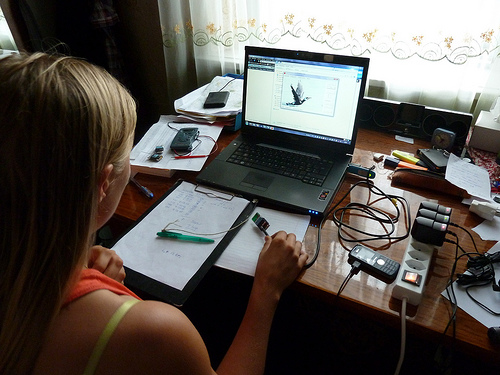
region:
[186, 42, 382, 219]
black laptop on desk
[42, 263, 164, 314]
girl has orange shirt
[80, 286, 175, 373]
girl has yellow bra strap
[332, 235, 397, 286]
cellphone charging on desk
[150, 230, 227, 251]
green ink pen on clip board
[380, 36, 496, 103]
curtain on the window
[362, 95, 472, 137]
docking station on desk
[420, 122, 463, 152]
small clock on desk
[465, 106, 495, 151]
box of tissues on desk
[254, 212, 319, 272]
girl is holding a cord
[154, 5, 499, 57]
floral white curtain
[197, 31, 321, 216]
laptop on the top of the table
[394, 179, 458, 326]
various charges on the electrical extension cord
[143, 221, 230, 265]
pen on the top of the clip board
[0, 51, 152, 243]
lady looking on the computer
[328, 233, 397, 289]
cellphone on the top of the table charging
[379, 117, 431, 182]
marker orange and yellow on the top of the table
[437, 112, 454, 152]
blue alarm clock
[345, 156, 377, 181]
USB plug on the computer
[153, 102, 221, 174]
recorder on the top of the paper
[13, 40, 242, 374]
young girl with green bra strap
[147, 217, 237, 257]
green ink pen on paper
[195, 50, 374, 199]
laptop with duck on the screen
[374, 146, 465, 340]
multiple outlet plug with 3 adapters in it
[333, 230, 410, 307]
cell phone charging on a desk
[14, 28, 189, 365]
young blonde girl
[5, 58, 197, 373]
blonde girl in orange top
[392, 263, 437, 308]
power light on electric outlet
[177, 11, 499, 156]
curtain with flowers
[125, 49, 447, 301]
multiple electronics on a desk together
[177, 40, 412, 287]
A laptop on the desk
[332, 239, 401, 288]
A cellphone on the desk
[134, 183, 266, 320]
A clipboard and pen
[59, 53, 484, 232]
Girl on the laptop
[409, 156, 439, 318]
A power strip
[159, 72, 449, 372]
Working on homework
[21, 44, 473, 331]
Studying for school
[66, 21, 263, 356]
Girl on the computer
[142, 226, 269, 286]
A pen on paper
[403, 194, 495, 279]
A charger in the power strip on the desk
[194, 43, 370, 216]
a black lap top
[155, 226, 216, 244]
a green ink pen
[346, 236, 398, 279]
a small cell phone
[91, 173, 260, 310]
a black clip board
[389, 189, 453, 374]
a white surge protector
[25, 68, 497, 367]
a brown wooden table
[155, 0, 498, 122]
a window with sheer white curtains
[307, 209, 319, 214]
blue lights on computer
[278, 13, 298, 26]
yellow flower decoration on curtains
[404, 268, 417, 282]
red power switch on surge protector